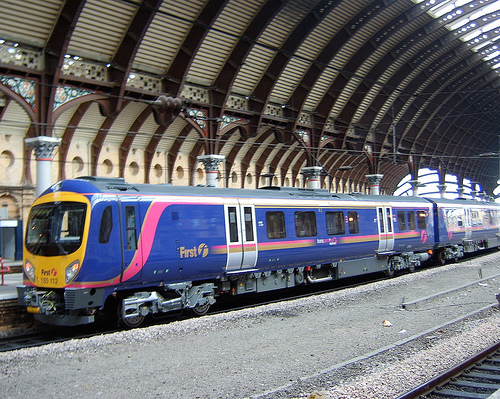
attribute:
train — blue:
[10, 148, 499, 317]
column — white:
[21, 83, 62, 186]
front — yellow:
[15, 181, 95, 293]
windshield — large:
[21, 194, 89, 254]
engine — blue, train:
[13, 172, 437, 324]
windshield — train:
[23, 195, 88, 263]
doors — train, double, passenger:
[222, 201, 257, 279]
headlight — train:
[62, 255, 82, 282]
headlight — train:
[20, 256, 35, 283]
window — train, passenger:
[262, 209, 286, 242]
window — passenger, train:
[291, 210, 318, 242]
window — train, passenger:
[322, 208, 345, 239]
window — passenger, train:
[346, 210, 359, 237]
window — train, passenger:
[394, 209, 409, 233]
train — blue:
[19, 170, 438, 320]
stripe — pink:
[71, 199, 221, 292]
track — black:
[429, 359, 485, 389]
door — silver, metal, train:
[215, 196, 275, 293]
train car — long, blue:
[24, 177, 456, 291]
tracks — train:
[7, 246, 498, 397]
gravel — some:
[1, 302, 64, 348]